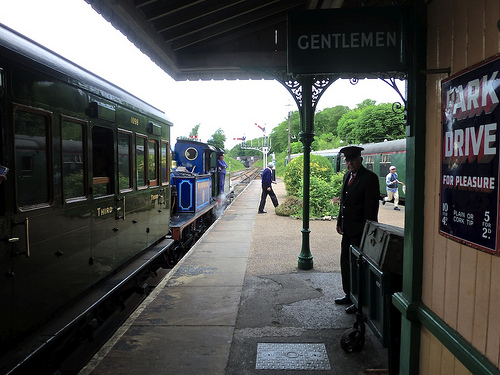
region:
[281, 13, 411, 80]
A painted wooden sign identifies the mens restroom entrance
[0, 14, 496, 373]
A small train station on an overcast day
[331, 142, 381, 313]
An elderly train conductor in uniform stares at the camera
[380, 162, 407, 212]
A man in a flat white cap and blue jacket runs to catch a train.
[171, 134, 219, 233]
A nicely painted blue coal train car.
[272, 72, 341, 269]
Roof support column with Victorian decoration.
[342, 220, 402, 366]
Newspaper vending machine.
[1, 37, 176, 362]
A green passenger train car.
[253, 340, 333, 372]
Metal maintenance access plate with a lifting ring in the sidewalk.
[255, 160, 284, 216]
A man in a blue sweater walks away from the train engine.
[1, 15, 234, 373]
A train in the foreground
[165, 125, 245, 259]
End of the train is blue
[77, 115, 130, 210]
Train window is open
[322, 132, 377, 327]
An older man in the foreground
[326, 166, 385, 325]
Man is wearing a suit and tie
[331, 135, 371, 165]
Man is wearing a black cap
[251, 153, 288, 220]
A person in the background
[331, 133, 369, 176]
Man is looking at the camera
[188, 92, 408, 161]
Tall trees in the background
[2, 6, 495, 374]
Photo was taken in the daytime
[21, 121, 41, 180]
a window on train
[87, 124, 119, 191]
.a window on train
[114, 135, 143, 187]
a window on train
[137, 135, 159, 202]
a window on train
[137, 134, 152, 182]
a window on train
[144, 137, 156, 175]
a window on train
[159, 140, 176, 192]
a window on train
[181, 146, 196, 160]
a window on train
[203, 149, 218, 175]
a window on train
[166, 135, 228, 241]
blue train on a rail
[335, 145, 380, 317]
conductor standing on the ground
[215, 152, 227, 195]
conductor wearing blue standing on train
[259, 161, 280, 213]
man in blue sweater walking away from train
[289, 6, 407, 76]
mens bathroom sign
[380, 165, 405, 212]
person running towards something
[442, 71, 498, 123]
the work park painted on sign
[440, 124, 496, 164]
the word drive printed on sign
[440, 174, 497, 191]
"for pleasure" written on sign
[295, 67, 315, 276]
pole supporting roof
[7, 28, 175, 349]
a brown train that stopped at the station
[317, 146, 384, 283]
an old man in a uniform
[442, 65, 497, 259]
a black and white sign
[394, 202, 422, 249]
the green border of a building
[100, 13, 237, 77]
the brown panel of the roof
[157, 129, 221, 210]
the blue caboose of a train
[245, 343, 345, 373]
a metal street covering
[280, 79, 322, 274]
a green pole that supports the roof